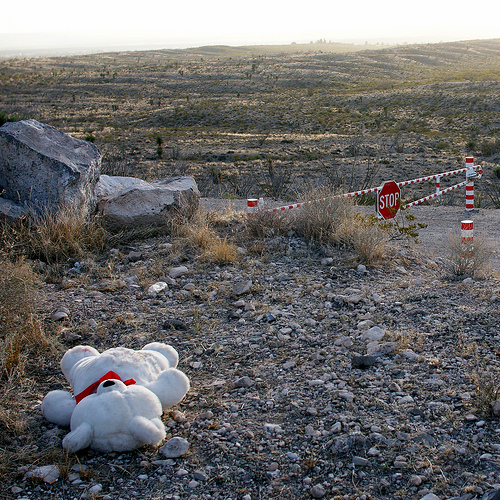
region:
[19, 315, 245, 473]
a white teddy bear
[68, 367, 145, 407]
a red ribbon around the bears neck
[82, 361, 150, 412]
the teddy bears black nose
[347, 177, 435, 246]
a red and white stop sign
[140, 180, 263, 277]
yellow dead grass patch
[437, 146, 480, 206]
a red and white pole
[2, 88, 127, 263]
a huge grey boulder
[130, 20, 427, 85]
the dusty mountains and hills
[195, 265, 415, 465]
rocks and gravel mixed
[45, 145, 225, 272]
a smaller beige boulder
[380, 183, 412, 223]
There is a stop sign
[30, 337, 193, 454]
White teddy bear laying on ground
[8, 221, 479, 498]
There are rocks on the ground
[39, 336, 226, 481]
Teddy bear has red ribbon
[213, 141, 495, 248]
red and white barrier gate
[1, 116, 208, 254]
There are two large rocks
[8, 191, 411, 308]
The grass is brown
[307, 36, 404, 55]
There are buildings in the far distance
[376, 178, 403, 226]
The sign is red and white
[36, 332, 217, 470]
The bear has a black nose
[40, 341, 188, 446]
White teddy bear lying on his back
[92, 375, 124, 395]
Nose of white teddy bear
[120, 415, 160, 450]
White teddy bear right ear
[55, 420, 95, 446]
White teddy bear left ear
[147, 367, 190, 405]
Right arm of white teddy bear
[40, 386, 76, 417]
Left arm of white teddy bear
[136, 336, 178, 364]
Right foot of white teddy bear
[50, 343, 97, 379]
Left foot of white teddy bear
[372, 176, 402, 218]
Red and white stop sign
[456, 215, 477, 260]
Orange and white post in ground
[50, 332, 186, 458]
this is a teddy bear doll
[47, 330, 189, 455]
the doll is white in color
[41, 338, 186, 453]
the doll is sleeping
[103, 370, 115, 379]
the doll has red ribbon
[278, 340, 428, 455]
the place is full of small rocks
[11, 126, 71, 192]
the rock is big in size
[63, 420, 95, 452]
the ear is big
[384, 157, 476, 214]
the post are red and white in color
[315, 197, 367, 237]
the grass are dry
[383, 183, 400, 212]
the stop sign is red in color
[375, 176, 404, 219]
a red stop sign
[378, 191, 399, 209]
white letters on the red sign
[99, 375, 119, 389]
the black nose of a teddy bear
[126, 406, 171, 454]
the ear of a teddy bear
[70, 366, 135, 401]
a red ribbon on the teddy bear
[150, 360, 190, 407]
the arm of a teddy bear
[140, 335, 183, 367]
the leg of a teddy bear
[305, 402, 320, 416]
a gray rock on the ground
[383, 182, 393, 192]
a bolt on the stop sign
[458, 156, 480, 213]
a red and white pole